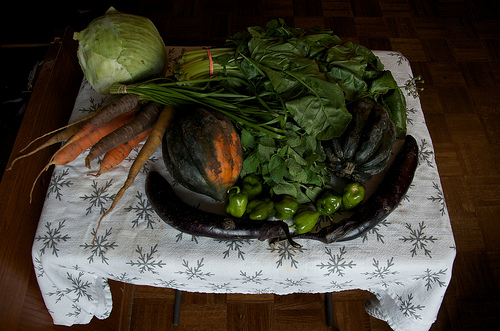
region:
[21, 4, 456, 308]
vegetables on a table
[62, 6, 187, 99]
a head of cabbage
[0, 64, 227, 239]
a bunch of dirty carrots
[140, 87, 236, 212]
an acorn squash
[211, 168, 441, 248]
a set of green peppers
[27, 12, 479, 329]
a white tablecloth with snowflakes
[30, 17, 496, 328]
a white tablecloth on the table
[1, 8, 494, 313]
a table on a brown floor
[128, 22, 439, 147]
a bunch of greens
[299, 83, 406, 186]
a green acorn squash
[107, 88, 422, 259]
plenty vegetable on table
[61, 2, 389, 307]
plenty vegetable on table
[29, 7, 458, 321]
a white cloth with silver snowflakes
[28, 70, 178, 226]
purple and orange carrots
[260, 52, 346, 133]
a green leaf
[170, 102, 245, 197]
a dark green and orange squash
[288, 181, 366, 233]
small green peppers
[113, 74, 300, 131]
green onions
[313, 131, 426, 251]
a long dark pepper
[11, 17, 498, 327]
a brown wood pattern floor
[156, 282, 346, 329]
the legs of a tray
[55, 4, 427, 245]
plenty vegetables on table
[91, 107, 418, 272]
plenty vegetables on table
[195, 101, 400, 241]
plenty vegetables on table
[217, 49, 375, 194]
green and leafy vegetables